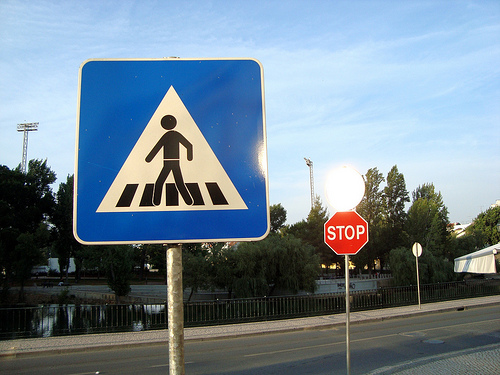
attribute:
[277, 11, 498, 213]
sky — blue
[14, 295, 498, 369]
road — two lane road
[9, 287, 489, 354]
sidewalk — on the side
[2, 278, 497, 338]
railings — metal, long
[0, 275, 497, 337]
rail — guard rail, metal , black 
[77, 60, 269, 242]
traffic sign — square, blue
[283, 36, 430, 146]
clouds — white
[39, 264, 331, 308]
water — in background, body of water, small 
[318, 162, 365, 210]
white light — large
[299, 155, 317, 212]
tower — cell phone tower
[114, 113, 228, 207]
figure — walking, of a person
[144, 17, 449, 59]
clouds — white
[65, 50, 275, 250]
sign — pedestrian walk sign, square, blue, white, pedestrian crossing sign, rectangle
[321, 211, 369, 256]
sign — stop sign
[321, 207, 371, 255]
sign — stop sign, octagon, red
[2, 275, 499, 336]
railing — iron, black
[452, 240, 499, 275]
canopy — white , large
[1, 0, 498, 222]
sky — blue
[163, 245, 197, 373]
pole — metal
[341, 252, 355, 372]
pole — metal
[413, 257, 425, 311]
pole — metal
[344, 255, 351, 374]
pole — metal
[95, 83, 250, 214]
triangle — white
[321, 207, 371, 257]
stop sign — white, red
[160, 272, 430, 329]
fence — iron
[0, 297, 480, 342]
lake — small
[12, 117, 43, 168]
lights — in background, metal arena lights, tall